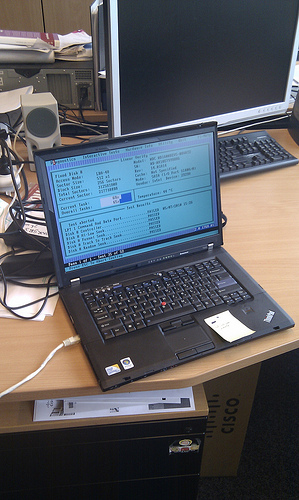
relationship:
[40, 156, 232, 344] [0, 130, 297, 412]
computer on desk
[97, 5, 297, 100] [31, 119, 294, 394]
monitor behind computer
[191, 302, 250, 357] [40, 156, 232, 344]
post it on computer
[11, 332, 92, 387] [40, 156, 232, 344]
cable in computer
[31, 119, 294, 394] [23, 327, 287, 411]
computer on desk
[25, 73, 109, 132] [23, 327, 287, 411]
speaker on desk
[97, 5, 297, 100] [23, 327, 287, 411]
monitor on desk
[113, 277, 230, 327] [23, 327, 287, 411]
keyboard on desk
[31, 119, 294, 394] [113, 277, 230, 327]
computer with keyboard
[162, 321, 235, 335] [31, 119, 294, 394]
button on computer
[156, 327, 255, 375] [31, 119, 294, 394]
mouse on computer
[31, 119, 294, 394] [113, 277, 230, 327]
computer has keyboard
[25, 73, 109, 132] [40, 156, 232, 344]
speaker for computer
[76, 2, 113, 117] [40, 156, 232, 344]
tower for computer